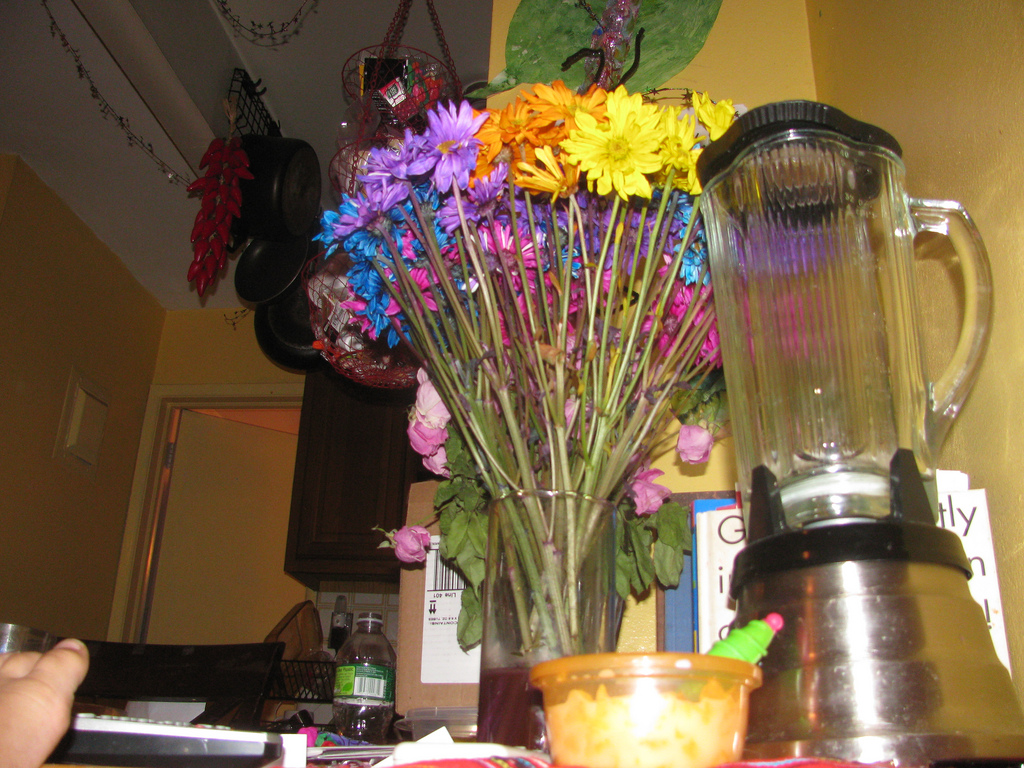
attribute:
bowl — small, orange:
[532, 647, 770, 762]